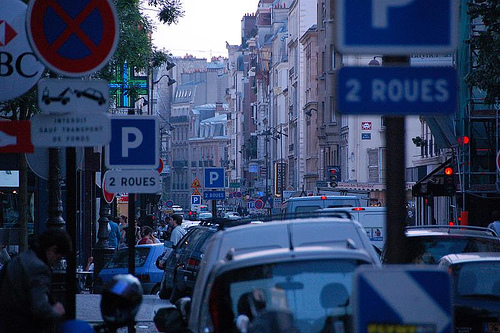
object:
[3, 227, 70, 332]
man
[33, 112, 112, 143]
sign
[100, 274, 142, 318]
helmet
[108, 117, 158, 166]
sign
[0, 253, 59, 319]
shirt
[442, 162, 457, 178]
traffic light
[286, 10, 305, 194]
building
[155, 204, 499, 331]
road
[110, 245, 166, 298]
car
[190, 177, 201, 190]
sign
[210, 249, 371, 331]
mirror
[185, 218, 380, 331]
van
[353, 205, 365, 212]
brake light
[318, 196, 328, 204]
brake light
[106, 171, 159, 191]
sign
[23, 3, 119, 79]
sign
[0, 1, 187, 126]
tree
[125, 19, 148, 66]
leaves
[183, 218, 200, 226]
car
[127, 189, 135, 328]
pole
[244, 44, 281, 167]
building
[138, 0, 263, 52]
sky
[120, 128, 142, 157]
writing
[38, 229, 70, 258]
hair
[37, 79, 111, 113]
sign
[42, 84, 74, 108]
truck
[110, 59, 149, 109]
cross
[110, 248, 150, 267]
windshield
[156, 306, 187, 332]
mirror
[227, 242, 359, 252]
rack